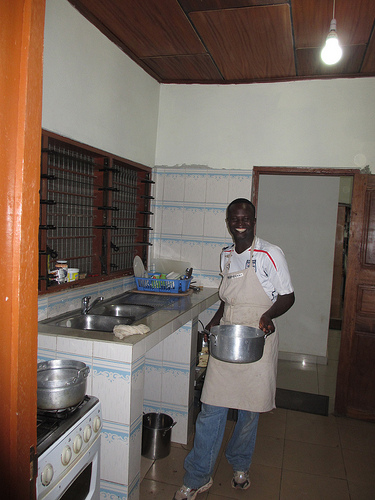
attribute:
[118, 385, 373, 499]
floor — here, tiled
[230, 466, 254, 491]
shoe — here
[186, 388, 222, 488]
leg — here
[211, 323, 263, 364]
pan — silver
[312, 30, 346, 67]
lightbulb — hanging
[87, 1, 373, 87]
ceiling — wood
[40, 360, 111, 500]
stove — white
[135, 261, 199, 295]
tray — blue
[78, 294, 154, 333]
sink — basined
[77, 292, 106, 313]
faucet — silver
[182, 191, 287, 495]
cook — smiling, standing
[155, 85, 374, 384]
wall — white, tiled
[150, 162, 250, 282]
tiles — blue